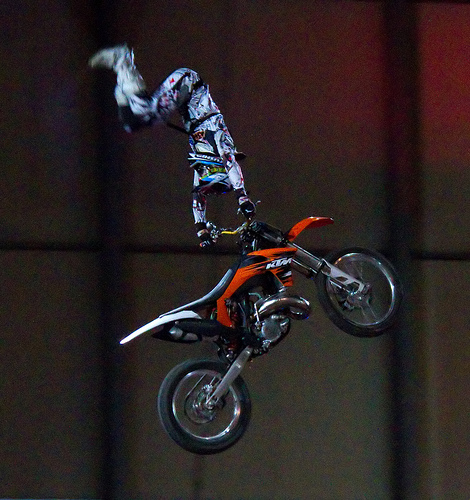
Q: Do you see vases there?
A: No, there are no vases.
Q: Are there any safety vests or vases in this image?
A: No, there are no vases or safety vests.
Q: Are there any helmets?
A: Yes, there is a helmet.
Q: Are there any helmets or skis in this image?
A: Yes, there is a helmet.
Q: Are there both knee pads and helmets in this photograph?
A: No, there is a helmet but no knee pads.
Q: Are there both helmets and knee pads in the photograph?
A: No, there is a helmet but no knee pads.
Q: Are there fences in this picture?
A: No, there are no fences.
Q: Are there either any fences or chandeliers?
A: No, there are no fences or chandeliers.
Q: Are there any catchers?
A: No, there are no catchers.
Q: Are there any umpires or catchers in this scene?
A: No, there are no catchers or umpires.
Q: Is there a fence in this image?
A: No, there are no fences.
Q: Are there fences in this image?
A: No, there are no fences.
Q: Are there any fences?
A: No, there are no fences.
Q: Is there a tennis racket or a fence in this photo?
A: No, there are no fences or rackets.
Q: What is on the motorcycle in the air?
A: The logo is on the motorcycle.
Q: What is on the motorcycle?
A: The logo is on the motorcycle.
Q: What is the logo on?
A: The logo is on the motorcycle.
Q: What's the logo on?
A: The logo is on the motorcycle.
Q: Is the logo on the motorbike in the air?
A: Yes, the logo is on the motorbike.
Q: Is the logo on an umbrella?
A: No, the logo is on the motorbike.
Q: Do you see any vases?
A: No, there are no vases.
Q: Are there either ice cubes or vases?
A: No, there are no vases or ice cubes.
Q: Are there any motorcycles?
A: Yes, there is a motorcycle.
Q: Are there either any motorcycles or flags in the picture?
A: Yes, there is a motorcycle.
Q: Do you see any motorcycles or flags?
A: Yes, there is a motorcycle.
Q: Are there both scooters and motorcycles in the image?
A: No, there is a motorcycle but no scooters.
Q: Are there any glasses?
A: No, there are no glasses.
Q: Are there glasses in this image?
A: No, there are no glasses.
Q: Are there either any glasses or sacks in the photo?
A: No, there are no glasses or sacks.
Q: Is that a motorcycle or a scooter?
A: That is a motorcycle.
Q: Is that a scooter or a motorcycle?
A: That is a motorcycle.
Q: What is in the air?
A: The motorcycle is in the air.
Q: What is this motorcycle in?
A: The motorcycle is in the air.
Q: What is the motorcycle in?
A: The motorcycle is in the air.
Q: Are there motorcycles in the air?
A: Yes, there is a motorcycle in the air.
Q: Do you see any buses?
A: No, there are no buses.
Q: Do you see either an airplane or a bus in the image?
A: No, there are no buses or airplanes.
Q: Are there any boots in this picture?
A: Yes, there are boots.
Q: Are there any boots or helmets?
A: Yes, there are boots.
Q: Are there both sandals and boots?
A: No, there are boots but no sandals.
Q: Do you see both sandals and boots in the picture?
A: No, there are boots but no sandals.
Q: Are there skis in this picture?
A: No, there are no skis.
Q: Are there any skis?
A: No, there are no skis.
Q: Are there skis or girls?
A: No, there are no skis or girls.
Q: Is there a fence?
A: No, there are no fences.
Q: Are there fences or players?
A: No, there are no fences or players.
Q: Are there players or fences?
A: No, there are no fences or players.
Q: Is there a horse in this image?
A: No, there are no horses.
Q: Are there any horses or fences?
A: No, there are no horses or fences.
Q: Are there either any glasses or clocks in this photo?
A: No, there are no glasses or clocks.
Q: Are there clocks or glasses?
A: No, there are no glasses or clocks.